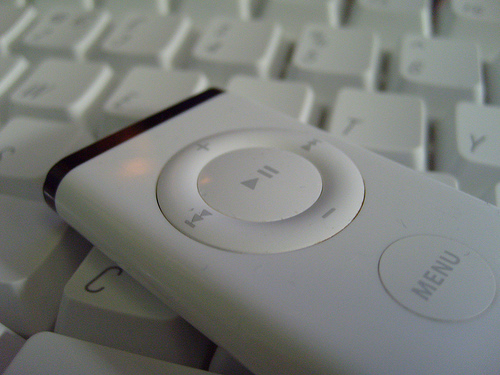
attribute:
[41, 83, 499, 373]
controler — white, apple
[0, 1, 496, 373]
keyboard — white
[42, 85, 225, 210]
top — black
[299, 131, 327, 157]
arrow — forward, next, gray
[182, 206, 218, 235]
arrow — rewind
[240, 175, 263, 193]
arrow — play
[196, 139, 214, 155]
plus — here, up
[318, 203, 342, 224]
minus — here, down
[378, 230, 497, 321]
menu — here, button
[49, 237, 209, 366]
button — c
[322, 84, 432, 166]
key — here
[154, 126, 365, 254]
button — round, white